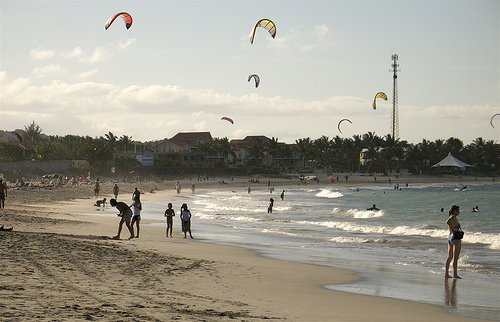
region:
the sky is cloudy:
[32, 44, 196, 125]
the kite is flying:
[218, 8, 292, 56]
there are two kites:
[92, 1, 309, 67]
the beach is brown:
[175, 240, 288, 304]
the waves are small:
[260, 185, 439, 287]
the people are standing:
[157, 190, 212, 245]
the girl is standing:
[430, 192, 483, 294]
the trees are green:
[15, 125, 116, 162]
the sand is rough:
[32, 222, 146, 314]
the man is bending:
[89, 179, 134, 247]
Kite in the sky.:
[102, 10, 132, 30]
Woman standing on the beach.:
[443, 202, 465, 279]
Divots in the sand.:
[12, 234, 61, 269]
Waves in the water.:
[330, 205, 365, 215]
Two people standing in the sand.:
[163, 203, 194, 239]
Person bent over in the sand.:
[109, 198, 135, 240]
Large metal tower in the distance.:
[385, 51, 401, 166]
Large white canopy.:
[432, 150, 474, 172]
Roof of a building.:
[155, 129, 216, 145]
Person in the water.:
[367, 202, 380, 213]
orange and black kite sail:
[102, 4, 142, 46]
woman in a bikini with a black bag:
[435, 199, 474, 279]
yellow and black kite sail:
[245, 7, 286, 49]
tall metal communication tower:
[386, 44, 411, 147]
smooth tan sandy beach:
[266, 252, 341, 316]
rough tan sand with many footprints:
[5, 239, 126, 320]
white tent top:
[425, 147, 471, 175]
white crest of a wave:
[331, 217, 420, 242]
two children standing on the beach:
[161, 192, 203, 249]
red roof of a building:
[167, 125, 212, 152]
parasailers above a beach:
[46, 10, 498, 272]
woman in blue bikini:
[431, 177, 473, 294]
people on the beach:
[45, 148, 300, 255]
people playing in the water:
[223, 168, 383, 239]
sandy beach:
[50, 239, 397, 309]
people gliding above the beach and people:
[86, 7, 467, 239]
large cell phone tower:
[376, 40, 419, 143]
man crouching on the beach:
[71, 169, 156, 251]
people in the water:
[466, 194, 489, 216]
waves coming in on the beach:
[249, 133, 491, 304]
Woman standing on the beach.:
[431, 198, 476, 285]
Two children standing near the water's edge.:
[155, 196, 205, 244]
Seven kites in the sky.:
[88, 4, 498, 141]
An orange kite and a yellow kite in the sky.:
[82, 2, 292, 53]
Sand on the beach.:
[4, 237, 245, 319]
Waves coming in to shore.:
[320, 216, 445, 246]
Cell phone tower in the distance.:
[378, 47, 414, 151]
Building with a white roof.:
[428, 148, 476, 175]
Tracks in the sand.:
[11, 230, 130, 312]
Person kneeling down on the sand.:
[89, 192, 111, 208]